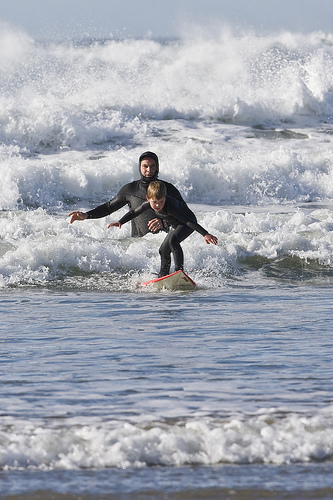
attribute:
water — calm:
[9, 287, 320, 316]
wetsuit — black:
[116, 199, 207, 276]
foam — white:
[4, 411, 327, 465]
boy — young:
[127, 186, 214, 271]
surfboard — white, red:
[143, 271, 200, 286]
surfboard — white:
[138, 269, 196, 289]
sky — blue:
[0, 0, 332, 39]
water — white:
[2, 34, 332, 486]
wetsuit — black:
[84, 180, 180, 242]